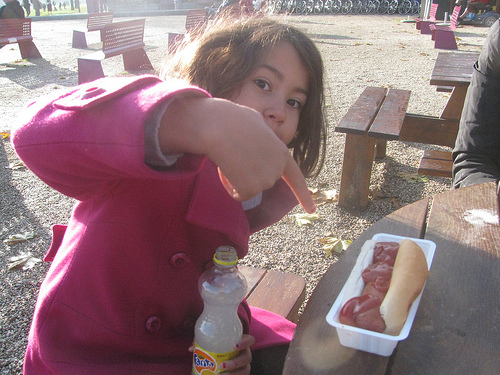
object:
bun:
[379, 239, 431, 336]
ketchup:
[339, 293, 385, 335]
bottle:
[191, 243, 248, 375]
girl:
[11, 16, 328, 375]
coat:
[14, 75, 312, 375]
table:
[284, 180, 499, 375]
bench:
[77, 18, 155, 86]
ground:
[0, 0, 500, 375]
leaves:
[320, 235, 353, 259]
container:
[324, 233, 437, 359]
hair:
[154, 12, 330, 179]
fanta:
[192, 351, 215, 368]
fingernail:
[307, 205, 317, 215]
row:
[255, 0, 423, 15]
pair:
[412, 0, 460, 50]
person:
[449, 17, 499, 194]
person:
[458, 0, 491, 21]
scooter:
[454, 0, 500, 27]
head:
[166, 15, 325, 146]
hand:
[159, 95, 318, 217]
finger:
[283, 149, 317, 214]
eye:
[253, 79, 273, 93]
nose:
[262, 92, 288, 121]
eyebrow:
[255, 64, 285, 79]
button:
[144, 316, 163, 333]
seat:
[334, 86, 411, 213]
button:
[169, 251, 189, 267]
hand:
[187, 334, 256, 375]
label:
[191, 343, 243, 375]